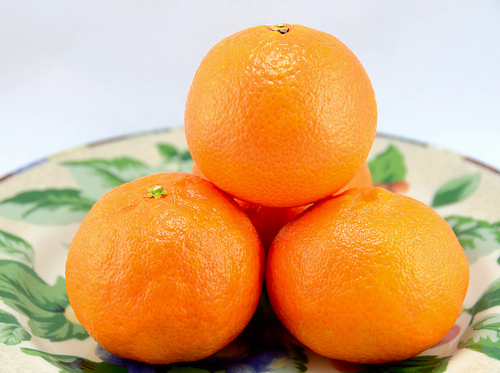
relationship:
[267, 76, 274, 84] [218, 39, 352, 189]
dimple on a peel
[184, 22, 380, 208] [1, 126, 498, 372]
fruit on a plate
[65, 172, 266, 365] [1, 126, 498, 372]
fruit on a plate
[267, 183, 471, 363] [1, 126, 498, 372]
fruit on a plate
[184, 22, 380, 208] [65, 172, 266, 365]
fruit on fruit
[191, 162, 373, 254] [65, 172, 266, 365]
orange behind fruit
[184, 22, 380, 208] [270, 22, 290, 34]
fruit has a nub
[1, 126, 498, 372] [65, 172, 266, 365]
plate under fruit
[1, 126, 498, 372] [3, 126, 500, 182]
plate has an edge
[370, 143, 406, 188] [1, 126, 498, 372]
leaf on a plate